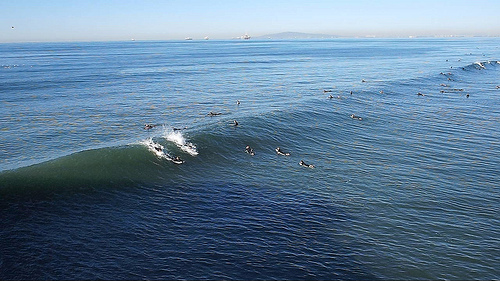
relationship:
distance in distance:
[0, 31, 500, 44] [4, 31, 498, 48]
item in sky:
[6, 21, 19, 35] [221, 3, 359, 26]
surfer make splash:
[158, 119, 209, 164] [130, 129, 171, 173]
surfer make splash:
[141, 134, 186, 175] [130, 129, 171, 173]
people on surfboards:
[238, 141, 320, 171] [277, 150, 289, 157]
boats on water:
[141, 111, 219, 185] [175, 174, 262, 240]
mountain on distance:
[248, 27, 497, 39] [0, 31, 500, 44]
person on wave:
[154, 139, 163, 151] [130, 109, 237, 196]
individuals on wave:
[86, 89, 288, 160] [174, 99, 372, 126]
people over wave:
[131, 102, 340, 171] [1, 50, 467, 228]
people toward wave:
[146, 110, 218, 137] [146, 86, 460, 207]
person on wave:
[229, 120, 239, 126] [1, 53, 498, 204]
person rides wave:
[167, 154, 184, 166] [3, 99, 391, 197]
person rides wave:
[230, 120, 240, 127] [3, 99, 391, 197]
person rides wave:
[245, 144, 257, 156] [3, 99, 391, 197]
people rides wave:
[297, 159, 316, 169] [3, 99, 391, 197]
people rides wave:
[143, 123, 157, 130] [3, 99, 391, 197]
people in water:
[297, 159, 316, 169] [210, 113, 371, 213]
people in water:
[275, 147, 292, 157] [3, 43, 498, 278]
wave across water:
[1, 58, 500, 199] [3, 43, 498, 278]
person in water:
[229, 120, 239, 126] [3, 43, 498, 278]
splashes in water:
[161, 127, 183, 142] [3, 43, 498, 278]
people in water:
[297, 159, 316, 169] [389, 150, 487, 220]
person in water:
[413, 90, 425, 98] [3, 43, 498, 278]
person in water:
[233, 99, 253, 113] [53, 53, 454, 235]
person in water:
[244, 144, 256, 155] [3, 43, 498, 278]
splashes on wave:
[142, 127, 198, 163] [14, 128, 221, 195]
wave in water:
[1, 53, 498, 204] [3, 43, 498, 278]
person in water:
[234, 97, 243, 111] [368, 109, 453, 199]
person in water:
[346, 112, 364, 123] [3, 43, 498, 278]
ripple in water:
[0, 61, 500, 278] [4, 5, 494, 272]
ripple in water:
[0, 61, 500, 278] [3, 43, 498, 278]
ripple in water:
[330, 216, 368, 258] [3, 43, 498, 278]